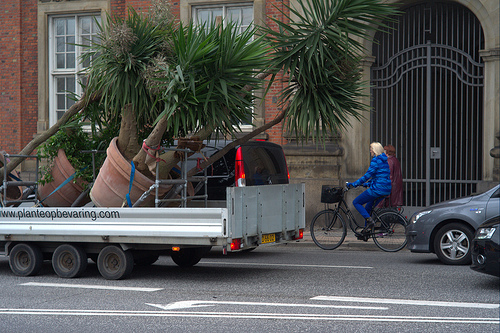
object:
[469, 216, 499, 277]
black car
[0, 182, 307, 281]
truck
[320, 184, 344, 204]
basket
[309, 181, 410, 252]
bicycle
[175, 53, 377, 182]
plant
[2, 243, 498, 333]
lane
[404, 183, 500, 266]
car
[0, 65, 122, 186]
plant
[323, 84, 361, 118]
stem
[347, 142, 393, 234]
lady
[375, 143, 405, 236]
lady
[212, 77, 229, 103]
stem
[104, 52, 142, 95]
stem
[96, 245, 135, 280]
wheel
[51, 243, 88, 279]
wheel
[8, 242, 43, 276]
wheel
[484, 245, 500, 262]
black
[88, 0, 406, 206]
potted trees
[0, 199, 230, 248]
flatbed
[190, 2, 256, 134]
window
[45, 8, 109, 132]
window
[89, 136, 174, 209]
flowerpot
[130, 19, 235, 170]
plant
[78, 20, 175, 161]
plant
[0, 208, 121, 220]
name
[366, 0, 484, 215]
metal gate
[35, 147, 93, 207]
pots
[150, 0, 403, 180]
plant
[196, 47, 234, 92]
stem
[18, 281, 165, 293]
line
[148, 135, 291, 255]
suv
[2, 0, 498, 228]
building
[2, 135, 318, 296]
truck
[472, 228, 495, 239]
headlight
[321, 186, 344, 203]
bag